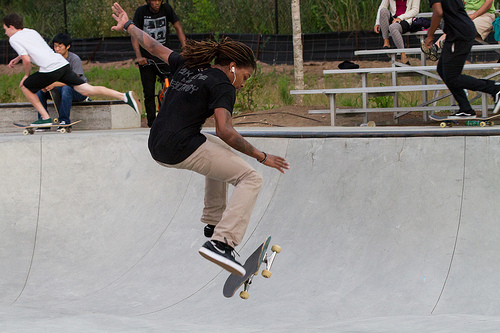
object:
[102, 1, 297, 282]
skateboarder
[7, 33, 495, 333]
skateboard park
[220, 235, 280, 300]
skateboard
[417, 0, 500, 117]
skateboarder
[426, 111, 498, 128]
skateboard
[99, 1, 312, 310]
trick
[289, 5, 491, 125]
stands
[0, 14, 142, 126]
person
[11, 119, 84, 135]
skateboard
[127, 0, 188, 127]
guy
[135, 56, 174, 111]
bike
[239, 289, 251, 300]
yellow wheels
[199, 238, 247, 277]
sneakers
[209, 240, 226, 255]
nike logo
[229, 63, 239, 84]
headphones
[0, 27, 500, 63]
fence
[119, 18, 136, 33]
watch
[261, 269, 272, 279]
wheel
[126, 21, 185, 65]
left arm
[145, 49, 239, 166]
shirt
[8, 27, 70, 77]
shirt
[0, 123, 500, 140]
edge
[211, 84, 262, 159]
right arm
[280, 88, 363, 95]
edge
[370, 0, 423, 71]
lady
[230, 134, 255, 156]
tattoo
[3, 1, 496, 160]
spectacle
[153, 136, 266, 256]
tan pants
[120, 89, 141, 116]
green shoes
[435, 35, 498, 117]
black pants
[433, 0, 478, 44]
gray shirt